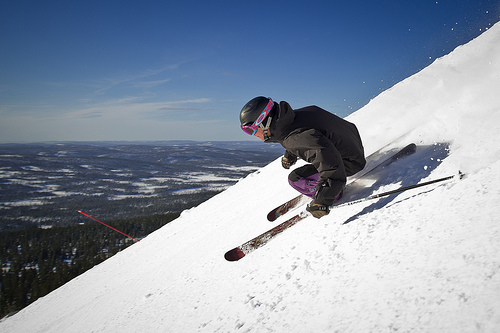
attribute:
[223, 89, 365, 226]
skier — leaning, skiing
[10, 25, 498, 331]
snow — white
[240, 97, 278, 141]
goggles — pink, purple, blue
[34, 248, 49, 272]
tree — green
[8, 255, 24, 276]
tree — green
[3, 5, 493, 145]
sky — blue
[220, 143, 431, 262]
skis — black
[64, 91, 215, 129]
clouds — white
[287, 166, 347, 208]
pants — purple, black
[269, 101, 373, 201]
jacket — black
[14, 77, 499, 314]
hill — snowy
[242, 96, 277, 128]
hat — black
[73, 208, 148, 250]
pole — red, sticking out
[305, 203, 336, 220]
glove — black